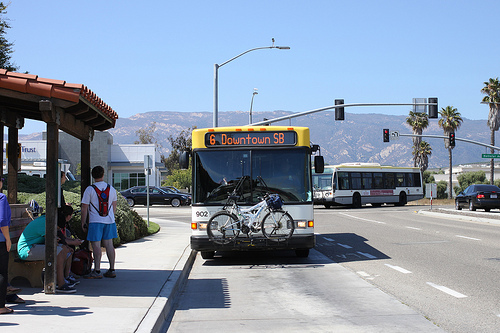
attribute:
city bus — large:
[187, 118, 322, 255]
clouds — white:
[110, 37, 171, 79]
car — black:
[448, 174, 500, 218]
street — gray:
[247, 283, 313, 315]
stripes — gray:
[383, 255, 470, 301]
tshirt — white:
[91, 194, 100, 221]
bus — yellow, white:
[321, 155, 428, 207]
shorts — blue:
[88, 222, 118, 241]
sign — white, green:
[414, 95, 440, 115]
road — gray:
[242, 272, 333, 314]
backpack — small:
[98, 193, 105, 208]